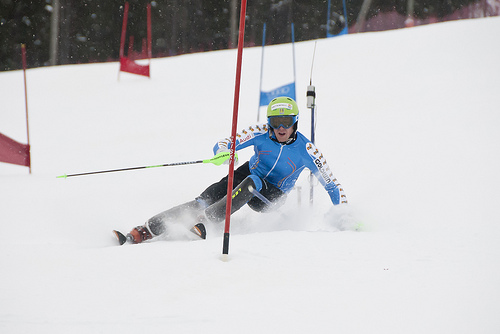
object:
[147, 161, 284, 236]
black pants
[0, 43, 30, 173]
flag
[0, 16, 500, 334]
ground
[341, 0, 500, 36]
hill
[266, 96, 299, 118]
helmet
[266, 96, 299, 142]
head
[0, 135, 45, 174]
sign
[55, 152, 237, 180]
skipole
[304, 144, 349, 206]
sleeve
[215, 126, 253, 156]
sleeve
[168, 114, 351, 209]
man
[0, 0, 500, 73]
background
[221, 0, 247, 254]
pole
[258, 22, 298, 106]
flag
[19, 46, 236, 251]
course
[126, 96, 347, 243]
man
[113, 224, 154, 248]
ski shoes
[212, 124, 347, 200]
jacket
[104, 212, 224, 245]
skiing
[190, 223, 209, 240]
ski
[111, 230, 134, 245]
ski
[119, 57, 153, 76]
sign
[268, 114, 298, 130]
goggles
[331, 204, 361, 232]
hand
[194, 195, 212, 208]
knee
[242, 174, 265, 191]
band